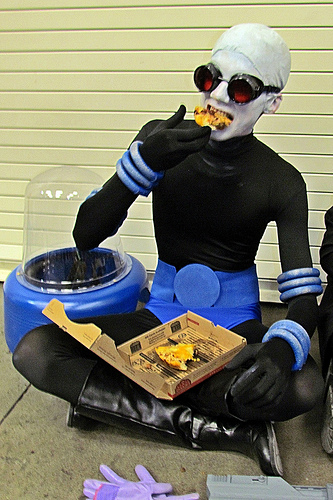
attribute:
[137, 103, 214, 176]
glove — black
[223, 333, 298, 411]
glove — black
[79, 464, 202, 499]
gloves — purple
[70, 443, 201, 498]
gloves — purple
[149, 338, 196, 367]
pizza — cheese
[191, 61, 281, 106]
goggles — dark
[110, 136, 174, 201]
bracelets — blue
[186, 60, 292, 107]
goggles — black, red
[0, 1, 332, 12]
line — white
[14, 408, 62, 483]
concrete — Small 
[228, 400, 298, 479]
boots — black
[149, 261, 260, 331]
shorts — blue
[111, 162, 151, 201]
bracelet — blue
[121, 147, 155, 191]
bracelet — blue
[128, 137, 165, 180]
bracelet — blue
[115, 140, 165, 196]
bracelets — blue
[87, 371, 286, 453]
boot — long, shiny, black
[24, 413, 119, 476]
pavement — cement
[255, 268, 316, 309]
rings — faded, blue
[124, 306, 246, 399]
box — small, brown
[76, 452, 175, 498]
gloves — purple 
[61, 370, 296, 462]
boot — tall, black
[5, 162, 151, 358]
helmet — plastic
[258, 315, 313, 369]
bracelets — blue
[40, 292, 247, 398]
pizza box — brown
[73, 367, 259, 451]
boots — black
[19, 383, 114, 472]
patch — Small , concrete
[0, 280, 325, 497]
concrete — Small 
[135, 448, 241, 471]
patch — Small 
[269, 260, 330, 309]
bracelets — blue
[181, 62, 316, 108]
goggles — black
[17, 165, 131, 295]
case — clear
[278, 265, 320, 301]
rings — blue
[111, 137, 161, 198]
rings — blue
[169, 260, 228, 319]
circle — blue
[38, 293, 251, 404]
box — card board, brown 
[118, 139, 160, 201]
bracelets — blue 